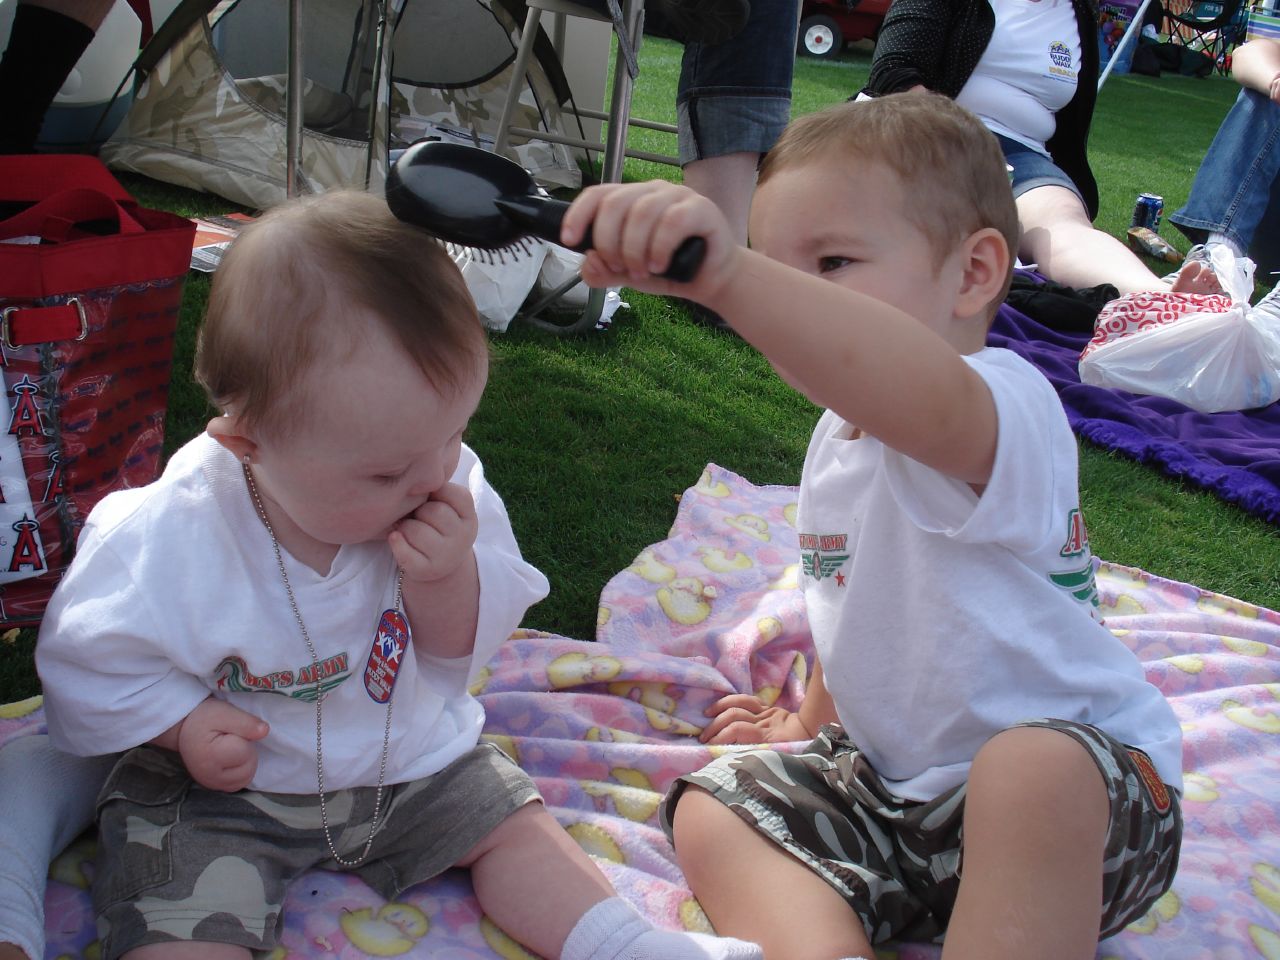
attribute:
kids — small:
[33, 82, 1190, 946]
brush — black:
[379, 124, 711, 277]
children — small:
[17, 56, 1271, 937]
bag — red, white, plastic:
[1076, 225, 1278, 424]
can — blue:
[1123, 190, 1176, 241]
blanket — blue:
[1024, 316, 1274, 511]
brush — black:
[386, 131, 716, 282]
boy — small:
[558, 82, 1187, 957]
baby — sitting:
[42, 172, 627, 950]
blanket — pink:
[6, 470, 1260, 958]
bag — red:
[0, 159, 190, 652]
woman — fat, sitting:
[849, 9, 1209, 301]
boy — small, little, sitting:
[372, 80, 1238, 952]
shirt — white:
[794, 347, 1188, 805]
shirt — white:
[35, 400, 557, 796]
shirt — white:
[972, 1, 1072, 138]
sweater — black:
[889, 13, 975, 89]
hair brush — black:
[407, 143, 560, 229]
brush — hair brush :
[328, 84, 677, 340]